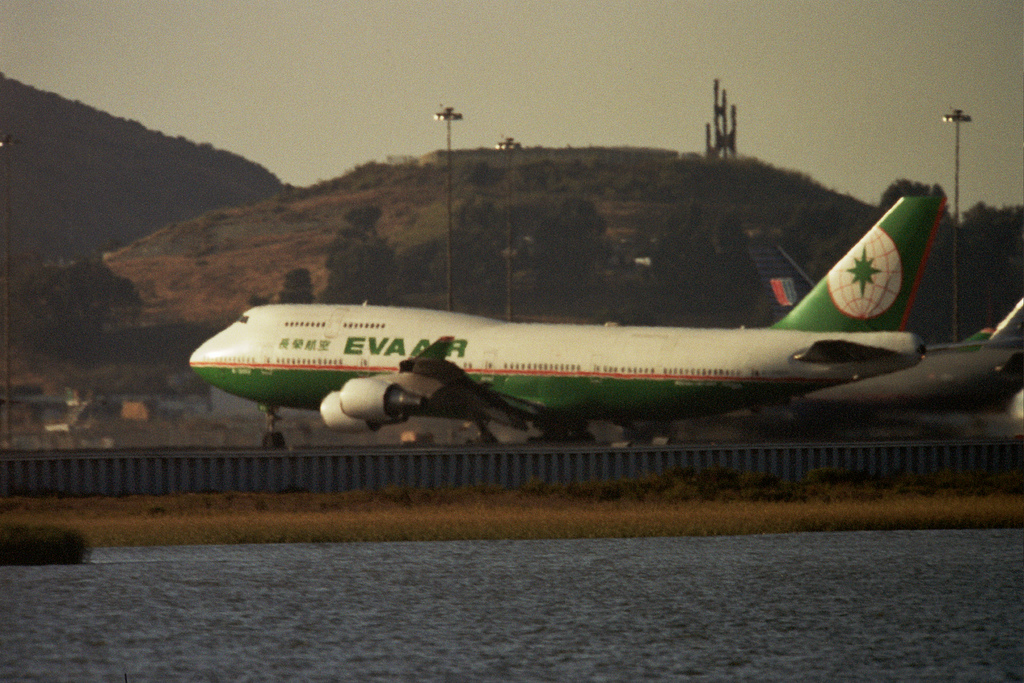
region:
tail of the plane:
[838, 225, 911, 324]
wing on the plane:
[394, 345, 443, 393]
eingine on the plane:
[355, 385, 426, 424]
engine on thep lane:
[295, 392, 344, 428]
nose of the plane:
[178, 338, 248, 389]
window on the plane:
[219, 315, 243, 325]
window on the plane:
[497, 358, 517, 366]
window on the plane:
[668, 369, 689, 377]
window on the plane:
[748, 363, 765, 384]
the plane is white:
[524, 326, 604, 355]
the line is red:
[539, 363, 625, 386]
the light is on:
[424, 105, 457, 131]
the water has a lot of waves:
[651, 584, 747, 649]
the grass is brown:
[209, 499, 267, 534]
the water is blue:
[329, 582, 405, 647]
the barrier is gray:
[234, 451, 308, 489]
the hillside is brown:
[163, 252, 222, 294]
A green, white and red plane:
[184, 198, 934, 392]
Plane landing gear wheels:
[251, 407, 286, 453]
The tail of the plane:
[781, 193, 943, 317]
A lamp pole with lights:
[427, 101, 467, 308]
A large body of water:
[96, 543, 1021, 680]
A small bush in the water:
[1, 511, 88, 568]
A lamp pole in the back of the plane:
[928, 104, 1009, 329]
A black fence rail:
[5, 435, 1020, 490]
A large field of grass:
[111, 470, 1009, 534]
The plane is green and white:
[103, 104, 1020, 519]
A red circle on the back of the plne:
[765, 123, 933, 412]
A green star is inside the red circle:
[722, 120, 931, 405]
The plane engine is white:
[248, 290, 515, 565]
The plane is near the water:
[49, 186, 895, 680]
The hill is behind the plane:
[332, 59, 987, 613]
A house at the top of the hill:
[437, 79, 596, 266]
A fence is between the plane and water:
[137, 265, 948, 617]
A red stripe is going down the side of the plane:
[144, 130, 910, 555]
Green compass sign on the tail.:
[825, 233, 898, 311]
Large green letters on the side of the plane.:
[339, 323, 403, 358]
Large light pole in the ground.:
[433, 89, 473, 299]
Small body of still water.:
[38, 514, 901, 598]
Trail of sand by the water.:
[157, 467, 496, 540]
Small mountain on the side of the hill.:
[0, 37, 356, 256]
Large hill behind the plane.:
[283, 130, 818, 276]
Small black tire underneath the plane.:
[248, 414, 291, 452]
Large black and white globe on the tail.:
[813, 218, 912, 352]